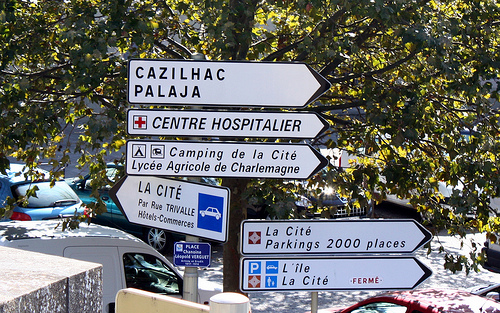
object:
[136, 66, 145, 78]
letter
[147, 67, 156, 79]
letter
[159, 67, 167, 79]
letter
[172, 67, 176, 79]
letter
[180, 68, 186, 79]
letter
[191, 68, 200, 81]
letter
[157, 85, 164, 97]
letter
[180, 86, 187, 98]
letter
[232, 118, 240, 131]
letter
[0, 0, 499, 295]
tree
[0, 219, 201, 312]
van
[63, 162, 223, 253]
cars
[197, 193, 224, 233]
picture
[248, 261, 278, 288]
pictures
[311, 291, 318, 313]
pole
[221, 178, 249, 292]
trunk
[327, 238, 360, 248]
number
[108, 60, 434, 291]
lot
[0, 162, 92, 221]
car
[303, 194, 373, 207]
hood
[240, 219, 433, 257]
sign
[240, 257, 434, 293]
sign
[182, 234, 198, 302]
pole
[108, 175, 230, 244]
sign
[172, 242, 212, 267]
sign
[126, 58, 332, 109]
sign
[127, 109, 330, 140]
sign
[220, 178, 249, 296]
pole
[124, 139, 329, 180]
sign